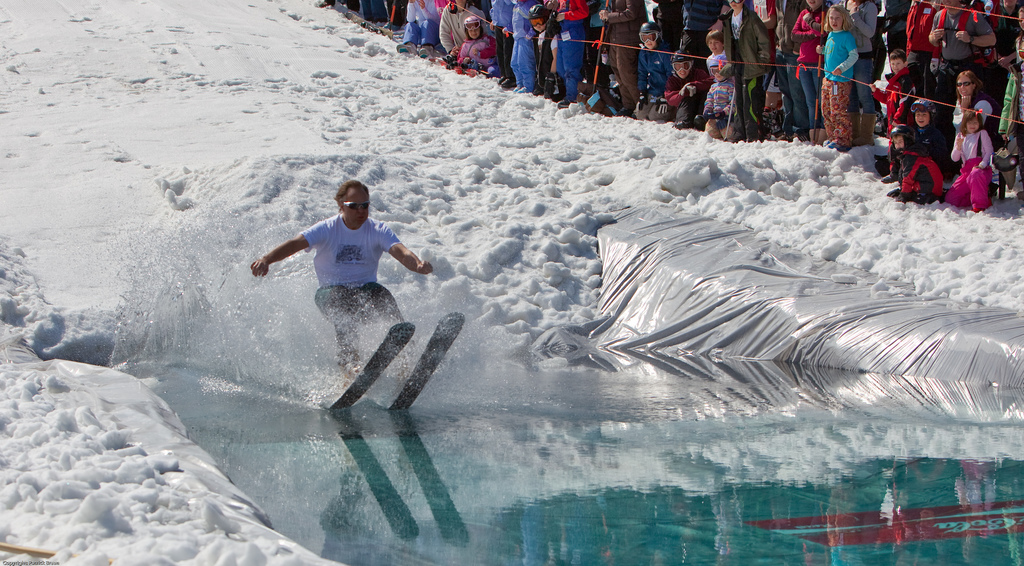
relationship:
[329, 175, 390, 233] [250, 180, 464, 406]
head on man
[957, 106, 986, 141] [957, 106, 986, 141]
head on person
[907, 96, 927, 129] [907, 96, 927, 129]
head on person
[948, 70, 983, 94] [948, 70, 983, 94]
head on person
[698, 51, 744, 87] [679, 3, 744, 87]
head on person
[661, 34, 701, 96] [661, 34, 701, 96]
head on person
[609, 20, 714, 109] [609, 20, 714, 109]
head on person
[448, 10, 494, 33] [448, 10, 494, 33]
head on person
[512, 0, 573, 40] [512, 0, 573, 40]
head on person